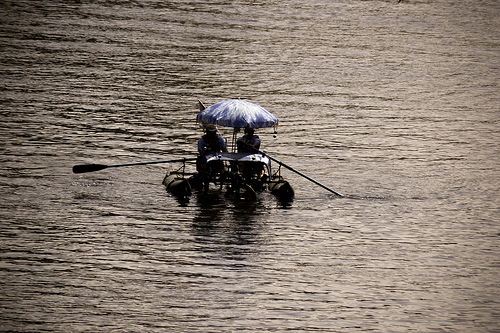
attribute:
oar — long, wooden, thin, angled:
[256, 147, 343, 188]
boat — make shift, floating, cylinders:
[163, 123, 296, 206]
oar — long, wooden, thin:
[69, 150, 195, 185]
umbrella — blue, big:
[199, 101, 283, 131]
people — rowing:
[195, 123, 264, 154]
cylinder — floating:
[265, 174, 296, 197]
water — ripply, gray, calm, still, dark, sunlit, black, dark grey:
[1, 2, 499, 332]